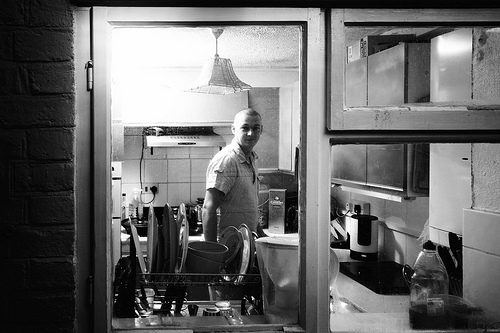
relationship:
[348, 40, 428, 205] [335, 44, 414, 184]
wood cabinets made out of wood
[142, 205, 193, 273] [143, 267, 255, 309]
plates in drainer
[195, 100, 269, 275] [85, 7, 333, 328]
man looking out window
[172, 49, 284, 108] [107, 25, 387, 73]
light attached to ceiling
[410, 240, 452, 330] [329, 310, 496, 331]
bottle on table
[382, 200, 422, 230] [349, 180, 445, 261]
tile on wall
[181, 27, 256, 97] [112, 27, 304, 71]
light fixture hanging from ceiling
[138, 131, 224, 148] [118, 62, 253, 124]
light under cabinet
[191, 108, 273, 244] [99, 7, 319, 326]
man looking out of window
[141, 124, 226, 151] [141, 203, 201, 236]
vent hood above stove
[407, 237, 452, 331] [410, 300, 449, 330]
bottle with liquid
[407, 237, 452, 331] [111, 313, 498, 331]
bottle on window sill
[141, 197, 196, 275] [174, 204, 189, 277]
plate next to plate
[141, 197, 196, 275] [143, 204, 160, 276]
plate next to plate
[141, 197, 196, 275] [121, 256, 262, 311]
plate on rack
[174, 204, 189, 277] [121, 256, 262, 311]
plate on rack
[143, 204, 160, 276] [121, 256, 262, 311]
plate on rack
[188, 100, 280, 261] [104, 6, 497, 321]
man in kitchen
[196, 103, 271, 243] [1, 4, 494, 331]
man in house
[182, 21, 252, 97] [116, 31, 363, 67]
light on ceiling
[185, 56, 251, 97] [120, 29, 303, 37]
light hanging from ceiling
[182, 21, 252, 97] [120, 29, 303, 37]
light hanging from ceiling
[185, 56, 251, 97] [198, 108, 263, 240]
light hanging over man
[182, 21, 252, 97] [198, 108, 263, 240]
light hanging over man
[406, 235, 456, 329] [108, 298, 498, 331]
glass bottle on counter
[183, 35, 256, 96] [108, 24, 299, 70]
light hanging from ceiling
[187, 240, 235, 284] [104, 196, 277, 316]
pot in drainer